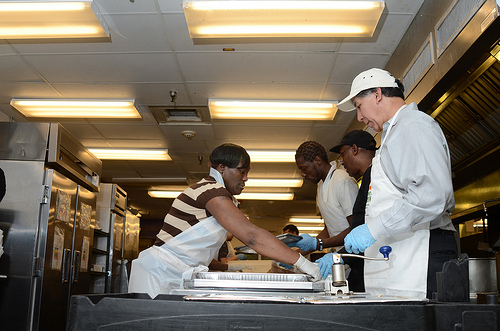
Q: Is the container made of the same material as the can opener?
A: Yes, both the container and the can opener are made of metal.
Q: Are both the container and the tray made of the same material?
A: Yes, both the container and the tray are made of metal.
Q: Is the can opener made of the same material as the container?
A: Yes, both the can opener and the container are made of metal.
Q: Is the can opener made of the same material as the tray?
A: Yes, both the can opener and the tray are made of metal.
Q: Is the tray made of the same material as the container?
A: Yes, both the tray and the container are made of metal.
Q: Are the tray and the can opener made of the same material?
A: Yes, both the tray and the can opener are made of metal.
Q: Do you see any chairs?
A: No, there are no chairs.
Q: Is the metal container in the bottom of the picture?
A: Yes, the container is in the bottom of the image.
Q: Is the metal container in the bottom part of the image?
A: Yes, the container is in the bottom of the image.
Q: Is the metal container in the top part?
A: No, the container is in the bottom of the image.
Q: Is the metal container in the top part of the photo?
A: No, the container is in the bottom of the image.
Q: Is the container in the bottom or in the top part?
A: The container is in the bottom of the image.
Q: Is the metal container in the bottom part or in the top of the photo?
A: The container is in the bottom of the image.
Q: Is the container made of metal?
A: Yes, the container is made of metal.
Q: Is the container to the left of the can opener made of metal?
A: Yes, the container is made of metal.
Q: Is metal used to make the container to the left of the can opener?
A: Yes, the container is made of metal.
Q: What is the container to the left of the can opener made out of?
A: The container is made of metal.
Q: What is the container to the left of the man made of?
A: The container is made of metal.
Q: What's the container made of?
A: The container is made of metal.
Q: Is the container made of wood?
A: No, the container is made of metal.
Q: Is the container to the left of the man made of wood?
A: No, the container is made of metal.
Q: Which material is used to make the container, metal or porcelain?
A: The container is made of metal.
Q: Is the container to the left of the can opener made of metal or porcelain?
A: The container is made of metal.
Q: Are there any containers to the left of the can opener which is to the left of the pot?
A: Yes, there is a container to the left of the can opener.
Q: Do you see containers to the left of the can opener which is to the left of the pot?
A: Yes, there is a container to the left of the can opener.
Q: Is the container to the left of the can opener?
A: Yes, the container is to the left of the can opener.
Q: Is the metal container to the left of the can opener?
A: Yes, the container is to the left of the can opener.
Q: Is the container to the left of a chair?
A: No, the container is to the left of the can opener.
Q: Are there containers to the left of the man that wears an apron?
A: Yes, there is a container to the left of the man.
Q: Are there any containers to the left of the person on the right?
A: Yes, there is a container to the left of the man.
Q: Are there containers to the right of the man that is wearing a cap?
A: No, the container is to the left of the man.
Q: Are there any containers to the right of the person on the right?
A: No, the container is to the left of the man.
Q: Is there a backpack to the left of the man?
A: No, there is a container to the left of the man.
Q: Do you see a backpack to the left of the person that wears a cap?
A: No, there is a container to the left of the man.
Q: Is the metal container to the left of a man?
A: Yes, the container is to the left of a man.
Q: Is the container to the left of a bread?
A: No, the container is to the left of a man.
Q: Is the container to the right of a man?
A: No, the container is to the left of a man.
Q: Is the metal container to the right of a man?
A: No, the container is to the left of a man.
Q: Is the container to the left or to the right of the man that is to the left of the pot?
A: The container is to the left of the man.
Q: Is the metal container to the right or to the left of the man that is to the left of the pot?
A: The container is to the left of the man.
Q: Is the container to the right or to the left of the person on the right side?
A: The container is to the left of the man.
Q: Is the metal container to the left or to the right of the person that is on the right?
A: The container is to the left of the man.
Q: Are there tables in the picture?
A: Yes, there is a table.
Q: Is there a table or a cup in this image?
A: Yes, there is a table.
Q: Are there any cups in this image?
A: No, there are no cups.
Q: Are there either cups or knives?
A: No, there are no cups or knives.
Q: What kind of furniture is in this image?
A: The furniture is a table.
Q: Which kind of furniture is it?
A: The piece of furniture is a table.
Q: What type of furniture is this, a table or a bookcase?
A: This is a table.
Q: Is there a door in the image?
A: Yes, there are doors.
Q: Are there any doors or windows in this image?
A: Yes, there are doors.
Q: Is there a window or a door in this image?
A: Yes, there are doors.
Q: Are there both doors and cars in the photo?
A: No, there are doors but no cars.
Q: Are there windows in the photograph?
A: No, there are no windows.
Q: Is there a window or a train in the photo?
A: No, there are no windows or trains.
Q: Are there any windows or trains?
A: No, there are no windows or trains.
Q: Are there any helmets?
A: No, there are no helmets.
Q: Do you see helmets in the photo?
A: No, there are no helmets.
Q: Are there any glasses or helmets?
A: No, there are no helmets or glasses.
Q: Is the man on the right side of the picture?
A: Yes, the man is on the right of the image.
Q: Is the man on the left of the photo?
A: No, the man is on the right of the image.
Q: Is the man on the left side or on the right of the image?
A: The man is on the right of the image.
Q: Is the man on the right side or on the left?
A: The man is on the right of the image.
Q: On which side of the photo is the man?
A: The man is on the right of the image.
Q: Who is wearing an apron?
A: The man is wearing an apron.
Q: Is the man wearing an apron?
A: Yes, the man is wearing an apron.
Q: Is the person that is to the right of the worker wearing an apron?
A: Yes, the man is wearing an apron.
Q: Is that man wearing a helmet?
A: No, the man is wearing an apron.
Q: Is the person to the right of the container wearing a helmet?
A: No, the man is wearing an apron.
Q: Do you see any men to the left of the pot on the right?
A: Yes, there is a man to the left of the pot.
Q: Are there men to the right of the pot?
A: No, the man is to the left of the pot.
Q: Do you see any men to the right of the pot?
A: No, the man is to the left of the pot.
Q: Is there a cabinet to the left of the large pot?
A: No, there is a man to the left of the pot.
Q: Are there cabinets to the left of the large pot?
A: No, there is a man to the left of the pot.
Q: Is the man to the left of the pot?
A: Yes, the man is to the left of the pot.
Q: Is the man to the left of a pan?
A: No, the man is to the left of the pot.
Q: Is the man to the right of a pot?
A: No, the man is to the left of a pot.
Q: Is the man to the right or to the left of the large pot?
A: The man is to the left of the pot.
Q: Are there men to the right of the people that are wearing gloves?
A: Yes, there is a man to the right of the people.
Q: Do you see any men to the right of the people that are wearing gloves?
A: Yes, there is a man to the right of the people.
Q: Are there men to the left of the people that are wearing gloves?
A: No, the man is to the right of the people.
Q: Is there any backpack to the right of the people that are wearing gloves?
A: No, there is a man to the right of the people.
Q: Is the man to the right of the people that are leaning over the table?
A: Yes, the man is to the right of the people.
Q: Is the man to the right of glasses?
A: No, the man is to the right of the people.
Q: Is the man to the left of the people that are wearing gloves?
A: No, the man is to the right of the people.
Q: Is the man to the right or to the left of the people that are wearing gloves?
A: The man is to the right of the people.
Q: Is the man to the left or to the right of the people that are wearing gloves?
A: The man is to the right of the people.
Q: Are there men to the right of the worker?
A: Yes, there is a man to the right of the worker.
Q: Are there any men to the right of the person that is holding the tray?
A: Yes, there is a man to the right of the worker.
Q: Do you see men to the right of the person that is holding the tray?
A: Yes, there is a man to the right of the worker.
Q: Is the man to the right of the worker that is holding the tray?
A: Yes, the man is to the right of the worker.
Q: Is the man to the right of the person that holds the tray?
A: Yes, the man is to the right of the worker.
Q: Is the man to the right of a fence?
A: No, the man is to the right of the worker.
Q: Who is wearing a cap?
A: The man is wearing a cap.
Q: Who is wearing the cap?
A: The man is wearing a cap.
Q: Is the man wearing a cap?
A: Yes, the man is wearing a cap.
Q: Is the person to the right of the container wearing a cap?
A: Yes, the man is wearing a cap.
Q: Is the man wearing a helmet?
A: No, the man is wearing a cap.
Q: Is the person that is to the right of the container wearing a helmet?
A: No, the man is wearing a cap.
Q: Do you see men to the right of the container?
A: Yes, there is a man to the right of the container.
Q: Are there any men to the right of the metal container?
A: Yes, there is a man to the right of the container.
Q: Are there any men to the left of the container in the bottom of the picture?
A: No, the man is to the right of the container.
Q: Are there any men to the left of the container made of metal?
A: No, the man is to the right of the container.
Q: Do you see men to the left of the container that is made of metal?
A: No, the man is to the right of the container.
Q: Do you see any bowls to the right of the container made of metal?
A: No, there is a man to the right of the container.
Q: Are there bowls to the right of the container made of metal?
A: No, there is a man to the right of the container.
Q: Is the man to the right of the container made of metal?
A: Yes, the man is to the right of the container.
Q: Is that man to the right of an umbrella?
A: No, the man is to the right of the container.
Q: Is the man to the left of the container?
A: No, the man is to the right of the container.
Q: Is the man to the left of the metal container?
A: No, the man is to the right of the container.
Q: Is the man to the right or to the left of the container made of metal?
A: The man is to the right of the container.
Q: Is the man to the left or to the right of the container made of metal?
A: The man is to the right of the container.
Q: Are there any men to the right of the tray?
A: Yes, there is a man to the right of the tray.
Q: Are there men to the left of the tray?
A: No, the man is to the right of the tray.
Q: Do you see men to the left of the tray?
A: No, the man is to the right of the tray.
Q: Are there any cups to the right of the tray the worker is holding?
A: No, there is a man to the right of the tray.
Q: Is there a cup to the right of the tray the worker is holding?
A: No, there is a man to the right of the tray.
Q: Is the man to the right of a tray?
A: Yes, the man is to the right of a tray.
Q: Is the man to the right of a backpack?
A: No, the man is to the right of a tray.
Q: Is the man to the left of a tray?
A: No, the man is to the right of a tray.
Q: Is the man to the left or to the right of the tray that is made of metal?
A: The man is to the right of the tray.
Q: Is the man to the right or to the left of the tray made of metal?
A: The man is to the right of the tray.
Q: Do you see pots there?
A: Yes, there is a pot.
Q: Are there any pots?
A: Yes, there is a pot.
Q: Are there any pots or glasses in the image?
A: Yes, there is a pot.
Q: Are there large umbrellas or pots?
A: Yes, there is a large pot.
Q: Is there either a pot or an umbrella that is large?
A: Yes, the pot is large.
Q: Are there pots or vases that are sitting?
A: Yes, the pot is sitting.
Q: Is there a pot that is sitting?
A: Yes, there is a pot that is sitting.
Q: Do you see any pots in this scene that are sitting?
A: Yes, there is a pot that is sitting.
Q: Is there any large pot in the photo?
A: Yes, there is a large pot.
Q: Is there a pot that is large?
A: Yes, there is a pot that is large.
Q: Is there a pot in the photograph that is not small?
A: Yes, there is a large pot.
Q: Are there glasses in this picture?
A: No, there are no glasses.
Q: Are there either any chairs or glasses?
A: No, there are no glasses or chairs.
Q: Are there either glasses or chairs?
A: No, there are no glasses or chairs.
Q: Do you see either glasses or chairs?
A: No, there are no glasses or chairs.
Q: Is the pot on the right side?
A: Yes, the pot is on the right of the image.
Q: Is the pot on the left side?
A: No, the pot is on the right of the image.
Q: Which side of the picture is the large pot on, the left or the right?
A: The pot is on the right of the image.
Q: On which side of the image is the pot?
A: The pot is on the right of the image.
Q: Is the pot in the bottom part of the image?
A: Yes, the pot is in the bottom of the image.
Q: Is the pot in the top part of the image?
A: No, the pot is in the bottom of the image.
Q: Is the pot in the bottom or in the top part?
A: The pot is in the bottom of the image.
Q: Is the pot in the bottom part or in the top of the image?
A: The pot is in the bottom of the image.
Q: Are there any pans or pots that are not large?
A: No, there is a pot but it is large.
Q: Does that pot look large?
A: Yes, the pot is large.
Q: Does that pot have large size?
A: Yes, the pot is large.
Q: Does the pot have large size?
A: Yes, the pot is large.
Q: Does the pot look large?
A: Yes, the pot is large.